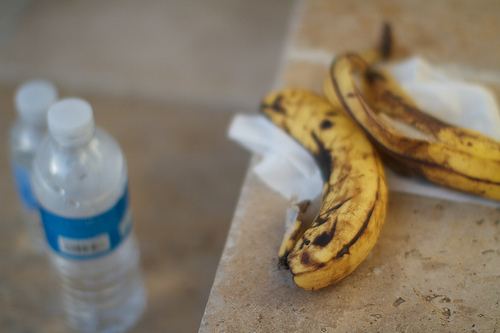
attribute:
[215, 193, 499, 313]
countertop — brown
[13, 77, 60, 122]
cap — white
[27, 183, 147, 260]
label — blue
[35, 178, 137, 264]
label — white, blue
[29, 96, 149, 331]
water bottle — plastic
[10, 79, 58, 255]
water bottle — plastic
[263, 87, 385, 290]
banana — browning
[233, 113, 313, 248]
stem — broken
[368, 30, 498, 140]
stem — broken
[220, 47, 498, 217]
napkin — white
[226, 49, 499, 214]
bag — clearish, white, plastic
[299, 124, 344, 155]
bruise — black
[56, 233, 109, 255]
code — upc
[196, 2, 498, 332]
stone — brown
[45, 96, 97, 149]
lid — plastic, white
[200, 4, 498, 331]
counter top — granite, light brown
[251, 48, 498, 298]
bananas — browning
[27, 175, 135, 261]
label — blue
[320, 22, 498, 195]
banana — very ripe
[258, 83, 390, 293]
banana — very ripe